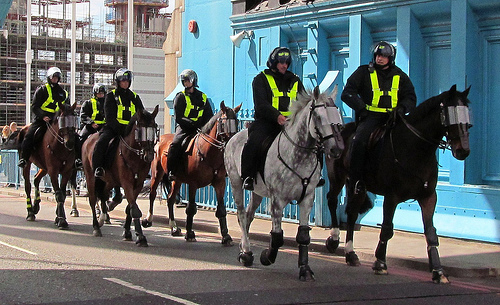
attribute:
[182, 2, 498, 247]
building — sky blue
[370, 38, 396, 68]
helmet — black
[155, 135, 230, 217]
horse — light brown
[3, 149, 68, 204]
gate — blue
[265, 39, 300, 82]
helmet — black, yellow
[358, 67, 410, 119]
safety vest — neon yellow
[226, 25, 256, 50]
speaker — white, loud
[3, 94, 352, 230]
gate — teal blue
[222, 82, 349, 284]
horse — grey, white and gray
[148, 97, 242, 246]
horse — ginger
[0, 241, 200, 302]
lane separator — white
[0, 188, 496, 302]
road — paved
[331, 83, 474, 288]
horse — black, brown, dark brown